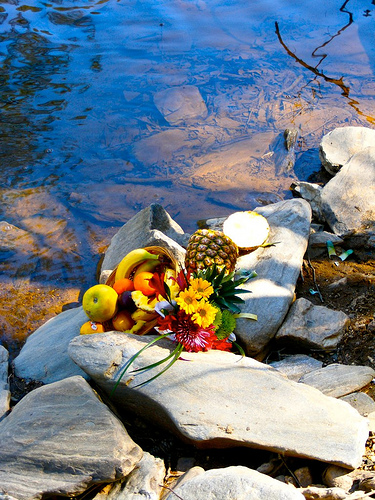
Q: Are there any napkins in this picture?
A: No, there are no napkins.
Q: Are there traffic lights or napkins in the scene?
A: No, there are no napkins or traffic lights.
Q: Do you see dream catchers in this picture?
A: No, there are no dream catchers.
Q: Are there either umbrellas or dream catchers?
A: No, there are no dream catchers or umbrellas.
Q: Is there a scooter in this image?
A: No, there are no scooters.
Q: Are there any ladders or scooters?
A: No, there are no scooters or ladders.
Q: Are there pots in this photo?
A: No, there are no pots.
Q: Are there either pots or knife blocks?
A: No, there are no pots or knife blocks.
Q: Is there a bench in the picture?
A: No, there are no benches.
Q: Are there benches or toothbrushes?
A: No, there are no benches or toothbrushes.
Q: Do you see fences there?
A: No, there are no fences.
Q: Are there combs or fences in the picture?
A: No, there are no fences or combs.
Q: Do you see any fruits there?
A: Yes, there is a fruit.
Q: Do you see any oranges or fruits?
A: Yes, there is a fruit.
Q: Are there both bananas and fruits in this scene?
A: Yes, there are both a fruit and a banana.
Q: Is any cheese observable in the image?
A: No, there is no cheese.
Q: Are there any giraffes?
A: No, there are no giraffes.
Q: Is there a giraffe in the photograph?
A: No, there are no giraffes.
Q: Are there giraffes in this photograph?
A: No, there are no giraffes.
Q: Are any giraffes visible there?
A: No, there are no giraffes.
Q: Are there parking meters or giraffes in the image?
A: No, there are no giraffes or parking meters.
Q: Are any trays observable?
A: No, there are no trays.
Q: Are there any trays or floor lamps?
A: No, there are no trays or floor lamps.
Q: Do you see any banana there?
A: Yes, there is a banana.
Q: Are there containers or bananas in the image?
A: Yes, there is a banana.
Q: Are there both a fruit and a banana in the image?
A: Yes, there are both a banana and a fruit.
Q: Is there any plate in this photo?
A: No, there are no plates.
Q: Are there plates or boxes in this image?
A: No, there are no plates or boxes.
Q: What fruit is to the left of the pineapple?
A: The fruit is a banana.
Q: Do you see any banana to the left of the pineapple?
A: Yes, there is a banana to the left of the pineapple.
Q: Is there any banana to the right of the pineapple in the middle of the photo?
A: No, the banana is to the left of the pineapple.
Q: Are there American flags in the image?
A: No, there are no American flags.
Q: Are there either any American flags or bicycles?
A: No, there are no American flags or bicycles.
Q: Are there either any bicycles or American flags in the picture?
A: No, there are no American flags or bicycles.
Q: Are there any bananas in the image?
A: Yes, there is a banana.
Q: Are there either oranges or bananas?
A: Yes, there is a banana.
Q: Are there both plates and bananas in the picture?
A: No, there is a banana but no plates.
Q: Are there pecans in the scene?
A: No, there are no pecans.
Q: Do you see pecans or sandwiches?
A: No, there are no pecans or sandwiches.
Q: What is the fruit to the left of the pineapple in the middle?
A: The fruit is a banana.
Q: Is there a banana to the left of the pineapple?
A: Yes, there is a banana to the left of the pineapple.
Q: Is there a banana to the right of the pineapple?
A: No, the banana is to the left of the pineapple.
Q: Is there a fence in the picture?
A: No, there are no fences.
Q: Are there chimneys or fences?
A: No, there are no fences or chimneys.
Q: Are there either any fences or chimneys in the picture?
A: No, there are no fences or chimneys.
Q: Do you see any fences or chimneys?
A: No, there are no fences or chimneys.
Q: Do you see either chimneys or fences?
A: No, there are no fences or chimneys.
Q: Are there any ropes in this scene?
A: No, there are no ropes.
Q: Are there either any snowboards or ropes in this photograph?
A: No, there are no ropes or snowboards.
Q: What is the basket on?
A: The basket is on the rock.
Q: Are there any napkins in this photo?
A: No, there are no napkins.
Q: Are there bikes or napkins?
A: No, there are no napkins or bikes.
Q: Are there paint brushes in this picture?
A: No, there are no paint brushes.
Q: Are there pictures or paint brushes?
A: No, there are no paint brushes or pictures.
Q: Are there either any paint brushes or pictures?
A: No, there are no paint brushes or pictures.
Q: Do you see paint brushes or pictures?
A: No, there are no paint brushes or pictures.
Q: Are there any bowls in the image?
A: No, there are no bowls.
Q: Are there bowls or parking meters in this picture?
A: No, there are no bowls or parking meters.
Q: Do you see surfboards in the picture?
A: No, there are no surfboards.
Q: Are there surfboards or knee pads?
A: No, there are no surfboards or knee pads.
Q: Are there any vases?
A: No, there are no vases.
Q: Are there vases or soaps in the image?
A: No, there are no vases or soaps.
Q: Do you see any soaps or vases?
A: No, there are no vases or soaps.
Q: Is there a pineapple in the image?
A: Yes, there is a pineapple.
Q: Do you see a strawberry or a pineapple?
A: Yes, there is a pineapple.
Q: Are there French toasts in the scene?
A: No, there are no French toasts.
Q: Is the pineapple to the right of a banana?
A: Yes, the pineapple is to the right of a banana.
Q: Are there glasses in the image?
A: No, there are no glasses.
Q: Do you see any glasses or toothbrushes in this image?
A: No, there are no glasses or toothbrushes.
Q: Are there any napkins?
A: No, there are no napkins.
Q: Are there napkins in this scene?
A: No, there are no napkins.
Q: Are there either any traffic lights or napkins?
A: No, there are no napkins or traffic lights.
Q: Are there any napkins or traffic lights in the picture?
A: No, there are no napkins or traffic lights.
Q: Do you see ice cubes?
A: No, there are no ice cubes.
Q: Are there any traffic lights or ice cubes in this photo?
A: No, there are no ice cubes or traffic lights.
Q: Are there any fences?
A: No, there are no fences.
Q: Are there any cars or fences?
A: No, there are no fences or cars.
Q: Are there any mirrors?
A: No, there are no mirrors.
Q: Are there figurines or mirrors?
A: No, there are no mirrors or figurines.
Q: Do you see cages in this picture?
A: No, there are no cages.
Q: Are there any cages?
A: No, there are no cages.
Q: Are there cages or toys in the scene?
A: No, there are no cages or toys.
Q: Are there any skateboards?
A: No, there are no skateboards.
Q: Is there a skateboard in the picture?
A: No, there are no skateboards.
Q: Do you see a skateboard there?
A: No, there are no skateboards.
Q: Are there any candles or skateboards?
A: No, there are no skateboards or candles.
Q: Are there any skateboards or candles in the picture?
A: No, there are no skateboards or candles.